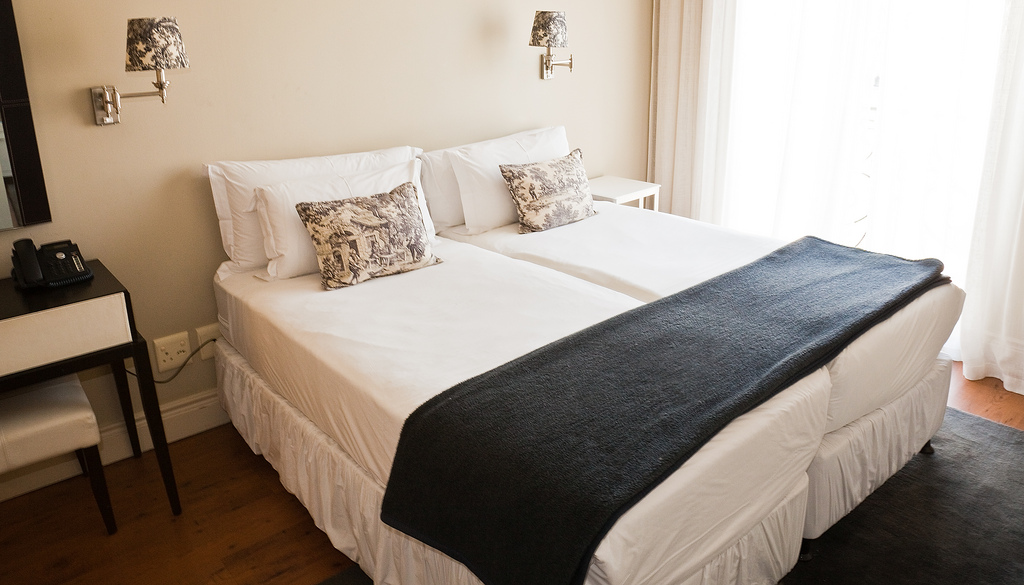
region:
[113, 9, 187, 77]
one black and white lampshade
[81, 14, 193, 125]
one nickel plated metal lamp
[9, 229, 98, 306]
one black telephone on desk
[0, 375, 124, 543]
right edge of white rectangular shaped bench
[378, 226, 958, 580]
black microfleece blanket on end of bed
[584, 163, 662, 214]
top of small rectangular shaped table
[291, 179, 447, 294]
one black and white toile print pillow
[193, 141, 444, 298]
three rectangular shaped pillows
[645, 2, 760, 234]
long white curtains hanging in sunlit window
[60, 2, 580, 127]
two metal swinging arm lamps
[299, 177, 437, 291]
There is a pillow on the bed.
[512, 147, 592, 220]
There is a pillow on the bed.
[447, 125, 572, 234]
There is a pillow on the bed.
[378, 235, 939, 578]
There is a black blanket on the bed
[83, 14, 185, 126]
There is a lamp on the wall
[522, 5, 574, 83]
There is a lamp on the wall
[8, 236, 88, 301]
There is phone on the desk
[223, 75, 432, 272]
a view of pillow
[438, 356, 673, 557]
a view of cloth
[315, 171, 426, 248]
a view of design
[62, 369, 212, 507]
a view of leg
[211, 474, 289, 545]
a view of floor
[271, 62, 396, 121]
a view of wall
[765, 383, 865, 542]
a view of gap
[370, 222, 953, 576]
the throw blanket is black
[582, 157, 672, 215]
the table beside the bed is white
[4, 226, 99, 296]
the phone is black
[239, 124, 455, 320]
a pillow on the bed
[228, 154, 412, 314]
a pillow on the bed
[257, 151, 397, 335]
a pillow on the bed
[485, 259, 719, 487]
a blanket on the bed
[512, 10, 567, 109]
a lamp on the wall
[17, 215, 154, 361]
a phone on the tablee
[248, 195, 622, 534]
sheets on the bed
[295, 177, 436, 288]
a black and white throw pillow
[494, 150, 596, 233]
a black and white throw pillow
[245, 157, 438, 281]
a white bed pillow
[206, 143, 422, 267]
a white bed pillow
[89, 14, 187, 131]
a wall mounted light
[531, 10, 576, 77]
a wall mounted light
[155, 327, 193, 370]
an electrical wall outlet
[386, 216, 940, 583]
black folded blanket at foot of bed